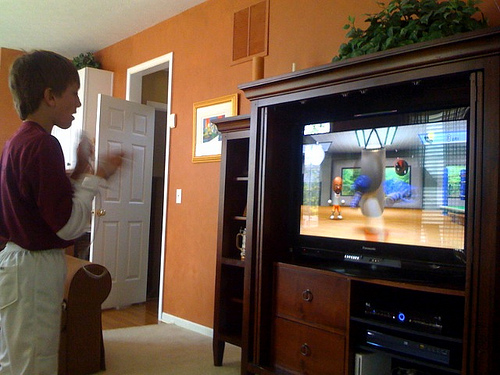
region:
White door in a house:
[85, 93, 169, 328]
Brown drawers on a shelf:
[261, 255, 352, 374]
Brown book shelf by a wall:
[199, 113, 269, 363]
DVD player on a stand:
[347, 276, 464, 370]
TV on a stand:
[286, 121, 492, 282]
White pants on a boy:
[7, 243, 94, 373]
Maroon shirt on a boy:
[6, 119, 96, 253]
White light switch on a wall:
[171, 186, 188, 208]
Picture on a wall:
[186, 90, 251, 158]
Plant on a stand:
[330, 3, 499, 59]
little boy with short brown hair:
[0, 33, 111, 374]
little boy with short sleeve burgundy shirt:
[6, 122, 172, 352]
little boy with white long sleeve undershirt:
[0, 51, 130, 248]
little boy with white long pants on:
[0, 40, 92, 372]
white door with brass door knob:
[81, 92, 172, 317]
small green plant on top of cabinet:
[52, 45, 118, 70]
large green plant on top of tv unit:
[301, 2, 482, 82]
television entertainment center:
[200, 51, 485, 371]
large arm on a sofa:
[0, 240, 151, 371]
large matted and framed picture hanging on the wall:
[169, 58, 257, 173]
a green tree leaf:
[369, 8, 382, 19]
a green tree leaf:
[386, 23, 396, 35]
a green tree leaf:
[338, 26, 352, 37]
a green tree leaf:
[336, 42, 348, 54]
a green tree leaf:
[461, 6, 478, 21]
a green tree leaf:
[425, 20, 434, 30]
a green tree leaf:
[401, 14, 418, 35]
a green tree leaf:
[425, 18, 440, 34]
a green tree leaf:
[359, 33, 375, 48]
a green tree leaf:
[395, 9, 409, 30]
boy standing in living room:
[6, 45, 138, 368]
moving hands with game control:
[72, 126, 141, 191]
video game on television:
[291, 118, 468, 246]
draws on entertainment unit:
[265, 267, 353, 373]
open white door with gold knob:
[71, 89, 171, 322]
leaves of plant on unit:
[335, 19, 435, 63]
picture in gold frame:
[183, 86, 241, 170]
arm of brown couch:
[64, 254, 116, 361]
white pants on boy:
[8, 241, 78, 363]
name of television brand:
[356, 239, 386, 256]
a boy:
[3, 50, 126, 373]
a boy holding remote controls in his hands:
[3, 34, 129, 374]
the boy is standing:
[3, 42, 124, 373]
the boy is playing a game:
[3, 40, 498, 373]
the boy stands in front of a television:
[8, 37, 490, 359]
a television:
[291, 120, 476, 273]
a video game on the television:
[285, 110, 485, 275]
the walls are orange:
[94, 8, 353, 356]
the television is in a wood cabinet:
[217, 68, 491, 373]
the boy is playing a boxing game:
[0, 52, 472, 367]